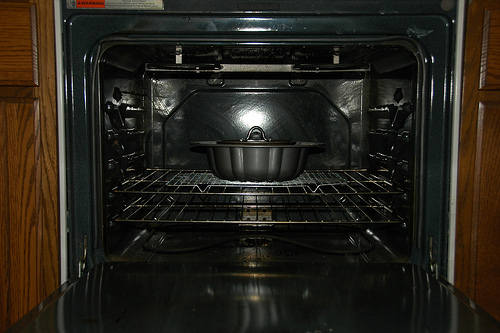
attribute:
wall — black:
[198, 92, 327, 119]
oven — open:
[62, 3, 467, 291]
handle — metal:
[237, 127, 277, 152]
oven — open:
[65, 24, 449, 267]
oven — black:
[4, 0, 499, 332]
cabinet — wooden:
[449, 0, 496, 321]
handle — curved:
[240, 124, 274, 143]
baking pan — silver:
[194, 127, 323, 180]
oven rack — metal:
[122, 157, 383, 255]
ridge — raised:
[101, 101, 144, 112]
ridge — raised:
[108, 128, 147, 140]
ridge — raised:
[108, 149, 147, 169]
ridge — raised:
[112, 169, 146, 197]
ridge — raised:
[110, 193, 145, 230]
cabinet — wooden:
[1, 1, 57, 331]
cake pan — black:
[191, 136, 322, 182]